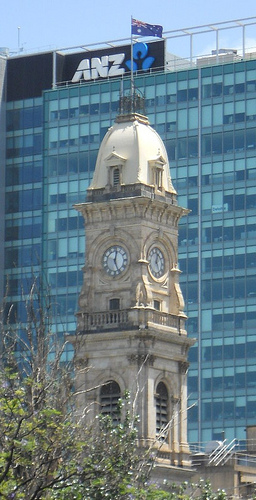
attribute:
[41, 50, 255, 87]
roof — white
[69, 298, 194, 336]
balcony — concrete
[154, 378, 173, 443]
window — arched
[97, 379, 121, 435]
window — arched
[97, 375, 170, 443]
blinds — wood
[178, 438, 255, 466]
fence — metal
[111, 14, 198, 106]
flag — russian, canadian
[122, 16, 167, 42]
flag — blue, white,and red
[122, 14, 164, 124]
flag — red, white, blue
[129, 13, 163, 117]
flag — national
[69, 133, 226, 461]
clock tower — old fashion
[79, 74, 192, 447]
building — brown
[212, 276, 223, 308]
window — glass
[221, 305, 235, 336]
window — glass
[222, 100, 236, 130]
window — glass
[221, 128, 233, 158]
window — glass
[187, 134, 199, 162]
window — glass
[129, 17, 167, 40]
flag — blue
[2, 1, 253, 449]
scraper — behind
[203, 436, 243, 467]
hand rails — metal, safety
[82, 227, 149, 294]
clock — showing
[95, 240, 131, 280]
clock — five p.m.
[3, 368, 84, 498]
leaves — green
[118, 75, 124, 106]
antenna — communication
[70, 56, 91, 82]
letter — white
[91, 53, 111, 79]
letter — white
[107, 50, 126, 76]
letter — white